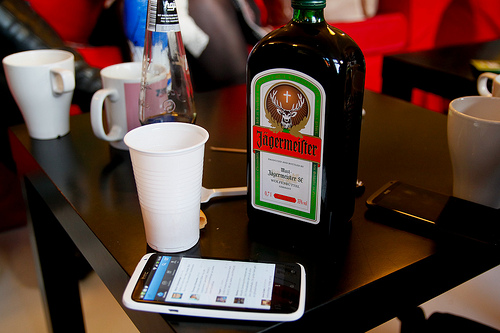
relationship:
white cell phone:
[189, 310, 223, 320] [117, 238, 283, 325]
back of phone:
[276, 267, 303, 305] [117, 238, 283, 325]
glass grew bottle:
[261, 65, 387, 167] [124, 24, 194, 81]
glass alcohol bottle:
[261, 65, 387, 167] [124, 24, 194, 81]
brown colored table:
[376, 229, 402, 267] [5, 127, 84, 231]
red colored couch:
[376, 25, 379, 34] [14, 0, 117, 53]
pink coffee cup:
[128, 86, 140, 99] [0, 50, 79, 141]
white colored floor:
[189, 310, 223, 320] [11, 269, 26, 299]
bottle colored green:
[124, 24, 194, 81] [261, 80, 311, 153]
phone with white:
[117, 238, 283, 325] [189, 310, 223, 320]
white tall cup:
[189, 310, 223, 320] [26, 33, 68, 121]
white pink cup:
[189, 310, 223, 320] [0, 50, 79, 141]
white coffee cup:
[189, 310, 223, 320] [0, 50, 79, 141]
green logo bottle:
[261, 80, 311, 153] [124, 24, 194, 81]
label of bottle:
[243, 79, 338, 225] [124, 24, 194, 81]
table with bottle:
[5, 127, 84, 231] [124, 24, 194, 81]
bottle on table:
[124, 24, 194, 81] [5, 127, 84, 231]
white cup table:
[189, 310, 223, 320] [5, 127, 84, 231]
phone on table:
[117, 238, 283, 325] [5, 127, 84, 231]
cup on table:
[0, 50, 79, 141] [5, 127, 84, 231]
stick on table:
[216, 143, 231, 155] [5, 127, 84, 231]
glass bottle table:
[261, 65, 387, 167] [5, 127, 84, 231]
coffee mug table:
[16, 44, 58, 65] [5, 127, 84, 231]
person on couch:
[188, 13, 250, 75] [14, 0, 117, 53]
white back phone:
[189, 310, 223, 320] [117, 238, 283, 325]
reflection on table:
[47, 159, 124, 202] [5, 127, 84, 231]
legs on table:
[28, 261, 94, 320] [5, 127, 84, 231]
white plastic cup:
[189, 310, 223, 320] [26, 33, 68, 121]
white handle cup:
[189, 310, 223, 320] [0, 50, 79, 141]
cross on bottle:
[277, 84, 291, 100] [124, 24, 194, 81]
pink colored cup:
[128, 86, 140, 99] [0, 50, 79, 141]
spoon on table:
[205, 177, 240, 222] [5, 127, 84, 231]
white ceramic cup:
[189, 310, 223, 320] [0, 50, 79, 141]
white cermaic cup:
[189, 310, 223, 320] [0, 50, 79, 141]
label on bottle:
[243, 79, 338, 225] [124, 24, 194, 81]